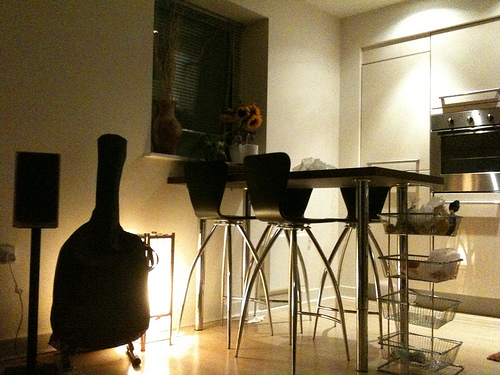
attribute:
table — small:
[175, 153, 430, 374]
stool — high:
[177, 156, 275, 341]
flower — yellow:
[227, 94, 281, 181]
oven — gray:
[423, 92, 498, 198]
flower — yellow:
[229, 104, 266, 136]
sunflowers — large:
[217, 101, 262, 142]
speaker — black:
[3, 140, 120, 361]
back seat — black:
[242, 152, 289, 222]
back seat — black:
[180, 155, 230, 217]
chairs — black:
[169, 141, 346, 371]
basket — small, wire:
[381, 247, 462, 280]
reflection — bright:
[153, 310, 208, 365]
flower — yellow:
[213, 103, 282, 131]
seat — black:
[183, 156, 260, 222]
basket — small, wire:
[380, 289, 459, 327]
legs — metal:
[195, 189, 415, 369]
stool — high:
[230, 153, 353, 373]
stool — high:
[238, 166, 318, 336]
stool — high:
[313, 166, 406, 366]